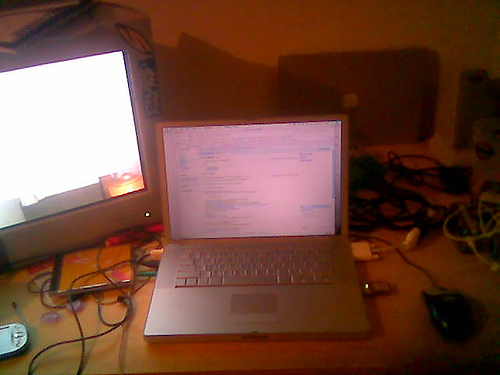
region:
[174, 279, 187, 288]
silver button on keyboard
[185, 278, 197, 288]
silver button on keyboard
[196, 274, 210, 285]
silver button on keyboard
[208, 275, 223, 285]
silver button on keyboard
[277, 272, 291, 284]
silver button on keyboard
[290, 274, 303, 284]
silver button on keyboard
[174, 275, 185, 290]
a key on a keyboard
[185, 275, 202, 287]
a key on a keyboard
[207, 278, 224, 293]
a key on a keyboard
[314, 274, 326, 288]
a key on a keyboard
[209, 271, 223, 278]
a key on a keyboard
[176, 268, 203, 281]
a key on a keyboard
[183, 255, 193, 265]
a key on a keyboard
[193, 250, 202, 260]
a key on a keyboard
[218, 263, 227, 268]
a key on a keyboard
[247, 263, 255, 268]
a key on a keyboard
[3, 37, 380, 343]
monitor and laptop next to each other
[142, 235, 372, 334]
silver keyboard on lower panel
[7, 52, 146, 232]
screen with bright light and orange picture in corner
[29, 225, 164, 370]
black wire looping over table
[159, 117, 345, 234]
blue and black print on screen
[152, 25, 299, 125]
shadow falling against the wall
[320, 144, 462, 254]
bundles of black wires behind laptop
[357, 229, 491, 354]
black wire connected to mouse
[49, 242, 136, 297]
orange CD case under wire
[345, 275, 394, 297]
small light on side of laptop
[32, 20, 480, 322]
these are computer screens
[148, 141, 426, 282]
this is a laptop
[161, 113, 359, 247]
the screen is on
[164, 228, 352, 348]
the laptop is on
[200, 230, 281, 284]
the keyboard is silver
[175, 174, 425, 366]
the laptop is an apple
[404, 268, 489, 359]
this is a mouse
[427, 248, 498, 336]
the mouse is black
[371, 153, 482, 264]
these are tangled wires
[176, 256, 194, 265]
silver button on keyboard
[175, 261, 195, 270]
silver button on keyboard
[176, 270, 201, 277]
silver button on keyboard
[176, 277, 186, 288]
silver button on keyboard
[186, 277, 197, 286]
silver button on keyboard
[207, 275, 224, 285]
silver button on keyboard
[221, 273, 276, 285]
silver button on keyboard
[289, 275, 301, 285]
silver button on keyboard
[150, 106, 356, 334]
A laptop on the table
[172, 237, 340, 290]
Keys on the keyboard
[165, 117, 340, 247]
A laptop screen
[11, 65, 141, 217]
A computer monitor screen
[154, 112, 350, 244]
laptop monitor is on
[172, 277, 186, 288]
key on open laptop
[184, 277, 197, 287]
key on open laptop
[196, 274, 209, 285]
key on open laptop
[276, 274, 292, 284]
key on open laptop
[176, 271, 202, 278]
key on open laptop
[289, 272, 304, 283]
key on open laptop